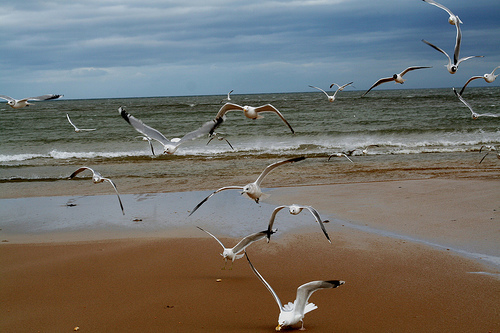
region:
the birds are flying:
[92, 79, 364, 331]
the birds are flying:
[83, 61, 255, 178]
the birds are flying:
[176, 154, 321, 324]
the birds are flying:
[269, 31, 499, 193]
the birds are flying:
[28, 89, 230, 189]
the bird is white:
[197, 212, 246, 267]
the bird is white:
[256, 269, 328, 331]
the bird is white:
[269, 180, 327, 246]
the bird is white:
[138, 118, 215, 162]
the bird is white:
[226, 93, 297, 156]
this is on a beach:
[25, 14, 494, 314]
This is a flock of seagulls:
[30, 68, 347, 293]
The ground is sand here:
[63, 228, 333, 327]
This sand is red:
[53, 246, 186, 327]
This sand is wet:
[24, 184, 274, 271]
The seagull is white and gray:
[254, 275, 342, 328]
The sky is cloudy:
[55, 15, 382, 110]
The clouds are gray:
[45, 12, 451, 144]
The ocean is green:
[82, 93, 449, 185]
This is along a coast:
[49, 67, 487, 257]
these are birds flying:
[110, 75, 337, 322]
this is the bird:
[263, 146, 311, 174]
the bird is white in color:
[239, 179, 260, 205]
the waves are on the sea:
[395, 130, 441, 157]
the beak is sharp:
[238, 188, 248, 194]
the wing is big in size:
[121, 107, 160, 144]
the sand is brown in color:
[81, 249, 186, 326]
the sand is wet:
[348, 187, 432, 270]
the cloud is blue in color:
[231, 4, 335, 70]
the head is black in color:
[391, 72, 398, 79]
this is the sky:
[214, 10, 298, 75]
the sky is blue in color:
[341, 23, 372, 31]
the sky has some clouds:
[56, 16, 166, 71]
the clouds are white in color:
[17, 10, 126, 82]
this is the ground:
[56, 248, 132, 319]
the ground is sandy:
[68, 245, 138, 311]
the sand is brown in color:
[52, 275, 142, 311]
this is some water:
[308, 104, 395, 136]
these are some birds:
[117, 93, 358, 329]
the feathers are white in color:
[278, 306, 300, 321]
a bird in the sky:
[208, 96, 301, 138]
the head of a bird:
[237, 180, 255, 197]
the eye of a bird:
[244, 185, 250, 192]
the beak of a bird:
[236, 188, 248, 198]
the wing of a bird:
[255, 99, 297, 135]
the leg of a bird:
[298, 317, 307, 332]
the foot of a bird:
[271, 323, 283, 331]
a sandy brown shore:
[0, 173, 497, 332]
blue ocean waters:
[2, 83, 497, 198]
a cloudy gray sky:
[0, 0, 499, 105]